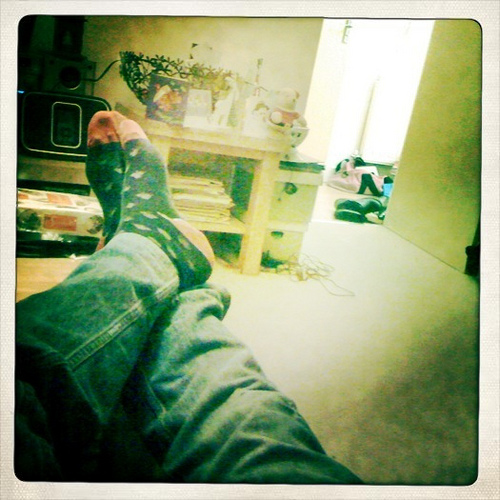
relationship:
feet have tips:
[108, 109, 217, 286] [112, 106, 149, 148]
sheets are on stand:
[167, 165, 235, 225] [16, 103, 284, 274]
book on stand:
[140, 73, 189, 130] [16, 103, 284, 274]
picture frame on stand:
[182, 84, 216, 133] [16, 103, 284, 274]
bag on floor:
[327, 151, 384, 200] [20, 180, 479, 485]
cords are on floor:
[260, 253, 353, 301] [20, 180, 479, 485]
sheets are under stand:
[167, 165, 235, 225] [16, 103, 284, 274]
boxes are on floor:
[234, 162, 324, 224] [20, 180, 479, 485]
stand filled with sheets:
[16, 103, 284, 274] [167, 165, 235, 225]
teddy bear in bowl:
[268, 81, 308, 130] [261, 115, 309, 153]